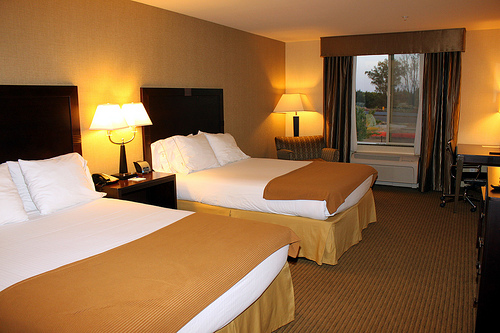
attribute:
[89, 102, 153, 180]
double lamp — on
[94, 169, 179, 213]
nightstand — dark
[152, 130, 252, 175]
pillows — white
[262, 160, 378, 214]
blanket — folded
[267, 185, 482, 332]
carpet — brown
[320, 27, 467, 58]
valance — brown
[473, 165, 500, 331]
dresser — brown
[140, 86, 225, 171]
headboard — brown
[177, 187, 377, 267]
dust ruffle — tan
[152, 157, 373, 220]
sheets — white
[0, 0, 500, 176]
walls — beige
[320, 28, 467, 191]
curtains — brown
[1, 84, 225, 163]
headboards — dark